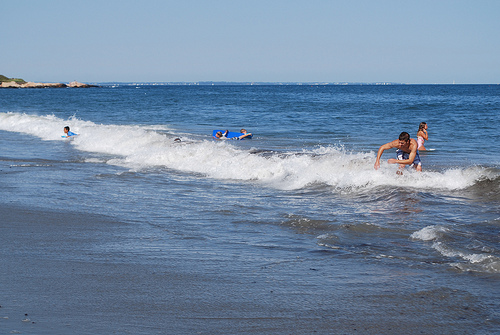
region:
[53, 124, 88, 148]
surfer in wave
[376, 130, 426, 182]
surfer in wave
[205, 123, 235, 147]
surfer in water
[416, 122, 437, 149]
swimmer in water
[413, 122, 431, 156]
girl in water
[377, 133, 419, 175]
boy in waves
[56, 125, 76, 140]
boy in waves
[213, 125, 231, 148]
person in waves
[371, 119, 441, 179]
people in waves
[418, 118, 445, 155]
surfer in water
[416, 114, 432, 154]
a young girl in the ocean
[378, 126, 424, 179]
a young man in the ocean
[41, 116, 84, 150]
a boy on a surf board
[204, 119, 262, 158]
a boy on a surf board in the ocean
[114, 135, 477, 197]
a white wave in the ocean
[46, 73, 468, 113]
a body of water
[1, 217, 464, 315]
a beach by the ocean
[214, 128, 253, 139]
a blue surf board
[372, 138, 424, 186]
a bent over in the water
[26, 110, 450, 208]
people in the water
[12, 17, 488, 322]
people in, over and behind wave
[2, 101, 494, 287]
long white wave close to shore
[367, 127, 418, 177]
man with bent elbows leaning over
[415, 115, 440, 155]
standing woman looking out to sea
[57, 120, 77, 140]
person in blue lying on surfboard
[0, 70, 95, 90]
low land jutting into ocean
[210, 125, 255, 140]
person sideways on blue surfboard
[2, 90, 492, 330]
blue water with gray patches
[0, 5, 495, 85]
clear light-blue sky over land on far side of ocean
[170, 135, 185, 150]
dark curve of hair on top of wave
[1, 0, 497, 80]
blue of daytime sky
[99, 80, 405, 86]
strip of land on horizon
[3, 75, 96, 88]
land with rock jetty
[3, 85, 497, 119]
ripples on water surface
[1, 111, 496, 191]
white water of crashed wave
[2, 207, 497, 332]
wet sand on shore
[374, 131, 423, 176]
man bent over wave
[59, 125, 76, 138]
boy in blue riding wave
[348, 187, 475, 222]
reflection on water surface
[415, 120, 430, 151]
woman facing away from shore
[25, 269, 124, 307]
sand on the shore line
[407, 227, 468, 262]
tiny wave coming to shore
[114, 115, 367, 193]
large waves crashing ashore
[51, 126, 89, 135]
surfer with blue clothing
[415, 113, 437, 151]
woman standing on skate board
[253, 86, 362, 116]
calm blue waters in the ocean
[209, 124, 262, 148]
man swimming towards the shore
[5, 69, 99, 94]
large rock in the distance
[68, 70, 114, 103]
houses on the rock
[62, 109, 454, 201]
people in the ocean water